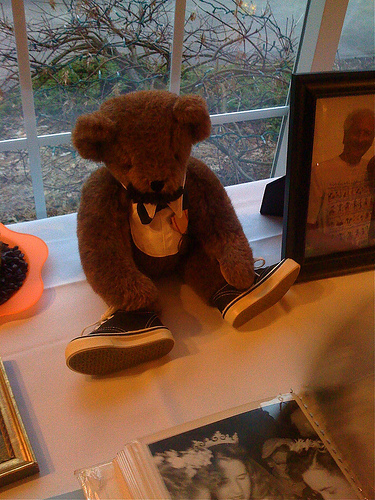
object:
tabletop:
[0, 270, 375, 500]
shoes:
[212, 256, 301, 329]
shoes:
[65, 305, 173, 375]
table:
[0, 174, 375, 500]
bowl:
[0, 223, 48, 317]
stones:
[0, 242, 28, 307]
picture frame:
[0, 359, 41, 487]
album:
[75, 388, 371, 500]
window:
[0, 0, 375, 227]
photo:
[302, 93, 375, 258]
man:
[306, 107, 373, 255]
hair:
[344, 108, 375, 143]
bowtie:
[126, 182, 185, 223]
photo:
[157, 396, 369, 498]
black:
[88, 262, 279, 335]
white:
[64, 257, 301, 375]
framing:
[0, 0, 375, 228]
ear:
[70, 113, 115, 163]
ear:
[172, 94, 210, 145]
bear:
[65, 89, 300, 375]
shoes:
[65, 257, 301, 375]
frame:
[260, 68, 375, 285]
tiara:
[193, 430, 240, 449]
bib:
[120, 174, 188, 258]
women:
[153, 430, 354, 500]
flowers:
[153, 448, 213, 494]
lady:
[149, 434, 291, 500]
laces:
[81, 306, 117, 335]